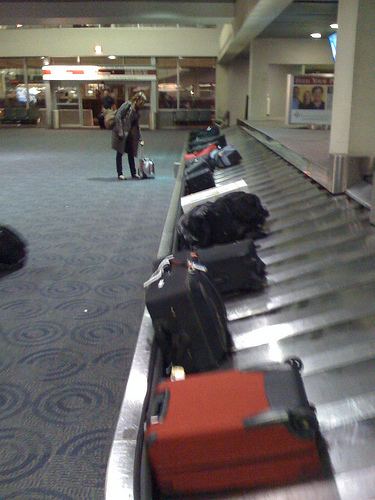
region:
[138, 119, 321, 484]
A row of traveling bags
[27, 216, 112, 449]
The ground floor is made out of carpet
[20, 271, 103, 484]
The carpet has a circular design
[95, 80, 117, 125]
A person is in the background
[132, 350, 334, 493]
Traveling bag is red and black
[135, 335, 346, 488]
Traveling bag in foreground has wheels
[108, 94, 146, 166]
Woman is wearing a coat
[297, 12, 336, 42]
Small lights are in the ceiling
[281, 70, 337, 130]
People are on a photo advertisement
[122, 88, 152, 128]
Woman's hair is light colored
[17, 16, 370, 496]
an airport terminal's baggage claim area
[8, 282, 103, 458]
curving pattern of carpet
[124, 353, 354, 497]
a red and white piece of luggage on a carousel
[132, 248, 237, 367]
a black piece of luggage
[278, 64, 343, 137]
a sign with an image on it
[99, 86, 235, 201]
woman standing near baggage carousel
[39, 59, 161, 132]
man standing in an entryway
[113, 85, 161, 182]
woman gripping the handle of a piece of luggage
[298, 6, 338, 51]
lights on the ceiling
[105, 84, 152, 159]
woman wearing a large coat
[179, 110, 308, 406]
The luggage is on the belt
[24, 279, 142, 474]
The floor has circles on it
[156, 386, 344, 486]
This suitcase is orange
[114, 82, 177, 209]
The lady is waiting for her bags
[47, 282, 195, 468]
The floor is dark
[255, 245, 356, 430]
The belt is made of metal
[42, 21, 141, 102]
the lights are on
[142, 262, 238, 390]
This bag is standing up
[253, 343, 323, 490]
The bag has wheels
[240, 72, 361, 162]
The walls are off white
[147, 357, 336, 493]
red suitcase with wheels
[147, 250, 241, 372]
black canvas suitcase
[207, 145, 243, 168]
light blue suitcase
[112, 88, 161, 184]
woman picking up a piece of luggage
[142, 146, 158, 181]
a woman's piece off luggage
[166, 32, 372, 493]
the baggage claim area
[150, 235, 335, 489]
three suitcases on a conveyor belt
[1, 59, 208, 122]
shop at an airport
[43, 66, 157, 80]
lit up store sign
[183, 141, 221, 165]
red luggage in the distance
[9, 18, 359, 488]
the baggage claim area of an airport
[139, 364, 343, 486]
a red luggage with a black handle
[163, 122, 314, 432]
a bunch of luggage waiting to be claimed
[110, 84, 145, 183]
a blond woman in a gray coat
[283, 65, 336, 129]
an advertisement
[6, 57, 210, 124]
a restaurant with huge windows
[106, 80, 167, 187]
a woman picking up her luggage at baggage claim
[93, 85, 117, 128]
a man carrying two luggage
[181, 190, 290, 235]
a black duffle bag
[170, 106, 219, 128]
three chairs